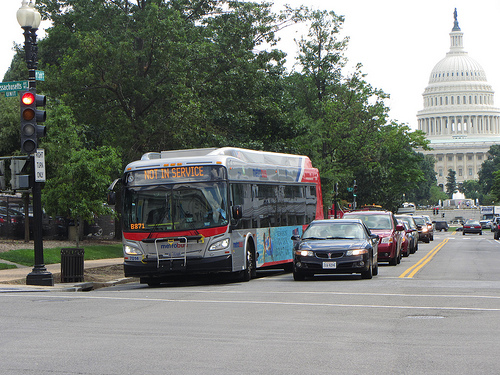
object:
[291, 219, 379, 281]
car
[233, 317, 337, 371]
street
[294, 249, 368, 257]
headlight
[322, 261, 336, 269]
license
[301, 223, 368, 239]
window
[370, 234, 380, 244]
side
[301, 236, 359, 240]
wiper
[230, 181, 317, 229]
windows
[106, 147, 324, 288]
bus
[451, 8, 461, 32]
statue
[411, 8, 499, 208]
building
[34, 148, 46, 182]
black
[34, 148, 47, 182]
sign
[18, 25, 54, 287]
pole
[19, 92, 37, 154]
signal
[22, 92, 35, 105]
light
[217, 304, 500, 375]
road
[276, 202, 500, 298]
traffic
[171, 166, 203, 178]
service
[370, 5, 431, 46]
background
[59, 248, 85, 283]
garbage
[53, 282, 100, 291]
corner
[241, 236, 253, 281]
wheel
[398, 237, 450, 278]
lines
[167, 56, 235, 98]
leaves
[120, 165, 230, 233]
windshield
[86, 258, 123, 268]
sidewalk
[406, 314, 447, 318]
manhole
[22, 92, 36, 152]
lights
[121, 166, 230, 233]
window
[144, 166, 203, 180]
words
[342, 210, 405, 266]
vehicle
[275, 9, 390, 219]
trees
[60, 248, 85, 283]
garbage can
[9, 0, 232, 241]
tree